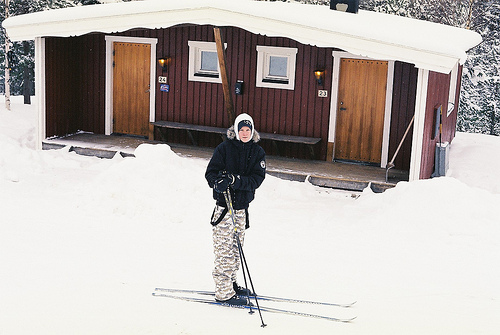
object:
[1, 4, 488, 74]
roof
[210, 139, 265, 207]
winter jacket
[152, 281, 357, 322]
skis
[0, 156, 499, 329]
snow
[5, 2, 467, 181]
house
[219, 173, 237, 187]
hands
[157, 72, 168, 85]
24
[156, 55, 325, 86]
lights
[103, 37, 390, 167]
doors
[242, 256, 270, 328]
ski poles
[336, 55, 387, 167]
door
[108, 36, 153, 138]
door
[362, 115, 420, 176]
shovel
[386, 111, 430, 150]
handle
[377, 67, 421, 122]
wall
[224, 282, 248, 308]
boots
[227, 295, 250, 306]
foot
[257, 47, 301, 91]
window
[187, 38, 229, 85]
window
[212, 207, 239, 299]
leg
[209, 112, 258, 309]
person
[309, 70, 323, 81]
light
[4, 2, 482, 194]
cabin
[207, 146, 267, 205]
jacket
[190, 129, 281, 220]
coat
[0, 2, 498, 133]
trees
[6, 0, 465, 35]
snow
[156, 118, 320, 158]
bench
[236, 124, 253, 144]
face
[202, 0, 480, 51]
snow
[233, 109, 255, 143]
head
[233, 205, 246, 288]
leg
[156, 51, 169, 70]
light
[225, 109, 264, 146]
hood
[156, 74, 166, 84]
sign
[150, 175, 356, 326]
skiing